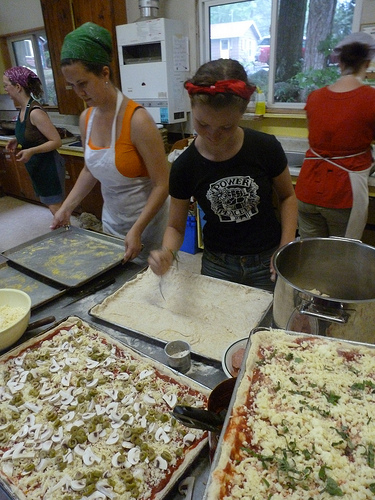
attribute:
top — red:
[298, 86, 374, 211]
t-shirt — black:
[171, 133, 288, 254]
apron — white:
[77, 104, 165, 240]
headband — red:
[182, 75, 255, 98]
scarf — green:
[58, 23, 114, 70]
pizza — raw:
[211, 323, 374, 499]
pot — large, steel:
[273, 229, 374, 341]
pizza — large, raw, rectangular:
[1, 320, 220, 499]